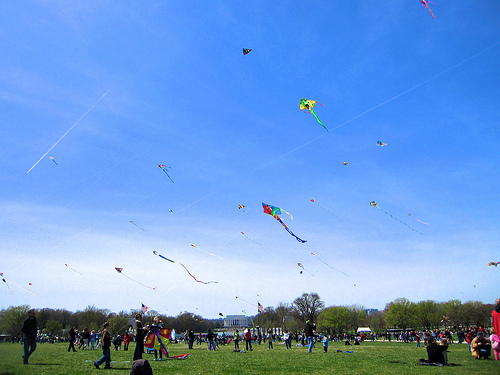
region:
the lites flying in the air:
[35, 0, 499, 292]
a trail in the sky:
[19, 140, 48, 188]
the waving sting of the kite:
[157, 253, 221, 290]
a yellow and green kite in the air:
[294, 89, 336, 137]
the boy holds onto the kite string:
[90, 319, 119, 373]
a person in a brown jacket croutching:
[469, 332, 491, 366]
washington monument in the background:
[222, 313, 251, 332]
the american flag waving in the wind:
[255, 301, 265, 326]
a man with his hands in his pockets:
[17, 304, 46, 366]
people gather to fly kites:
[17, 295, 262, 374]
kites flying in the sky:
[18, 1, 452, 294]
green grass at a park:
[235, 355, 400, 370]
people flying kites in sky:
[92, 308, 184, 370]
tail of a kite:
[277, 221, 313, 248]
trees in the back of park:
[334, 297, 468, 329]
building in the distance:
[218, 303, 254, 333]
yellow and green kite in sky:
[294, 94, 333, 131]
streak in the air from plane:
[21, 113, 83, 181]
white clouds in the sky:
[72, 267, 124, 297]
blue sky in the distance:
[435, 112, 487, 215]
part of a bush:
[375, 308, 387, 323]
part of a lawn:
[296, 352, 308, 367]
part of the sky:
[360, 199, 367, 215]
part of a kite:
[157, 247, 165, 262]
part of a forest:
[405, 306, 420, 309]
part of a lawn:
[191, 335, 206, 365]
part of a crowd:
[408, 313, 428, 335]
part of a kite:
[285, 223, 302, 241]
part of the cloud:
[333, 180, 361, 194]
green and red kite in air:
[265, 195, 305, 237]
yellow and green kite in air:
[290, 77, 335, 132]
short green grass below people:
[59, 326, 296, 373]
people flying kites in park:
[0, 41, 497, 363]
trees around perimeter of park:
[25, 295, 450, 360]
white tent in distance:
[351, 327, 370, 335]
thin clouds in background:
[48, 204, 488, 352]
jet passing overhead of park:
[9, 105, 89, 192]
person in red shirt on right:
[473, 302, 498, 339]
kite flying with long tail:
[143, 236, 222, 293]